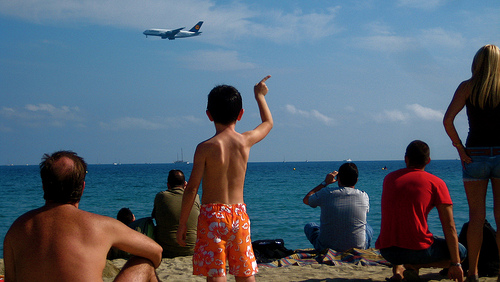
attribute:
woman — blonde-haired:
[440, 42, 495, 279]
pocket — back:
[459, 156, 481, 176]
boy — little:
[174, 74, 276, 279]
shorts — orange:
[192, 203, 258, 276]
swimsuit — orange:
[184, 200, 263, 276]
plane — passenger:
[132, 6, 212, 46]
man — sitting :
[302, 158, 372, 255]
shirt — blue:
[308, 185, 368, 250]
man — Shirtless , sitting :
[6, 150, 171, 280]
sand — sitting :
[100, 245, 497, 280]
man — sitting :
[377, 140, 466, 277]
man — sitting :
[148, 162, 201, 254]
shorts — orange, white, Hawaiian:
[181, 195, 300, 272]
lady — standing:
[439, 43, 499, 279]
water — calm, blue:
[250, 147, 303, 232]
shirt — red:
[393, 165, 428, 194]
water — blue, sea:
[97, 160, 157, 195]